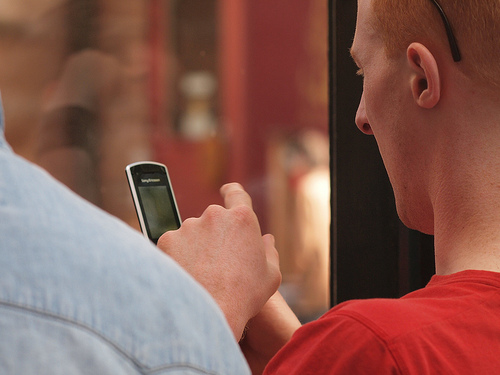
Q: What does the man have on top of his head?
A: Glasses.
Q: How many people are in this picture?
A: 2.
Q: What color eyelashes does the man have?
A: Red.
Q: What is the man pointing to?
A: Cell phone.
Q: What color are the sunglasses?
A: Black.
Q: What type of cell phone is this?
A: Flip phone.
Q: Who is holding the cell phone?
A: Man in red.